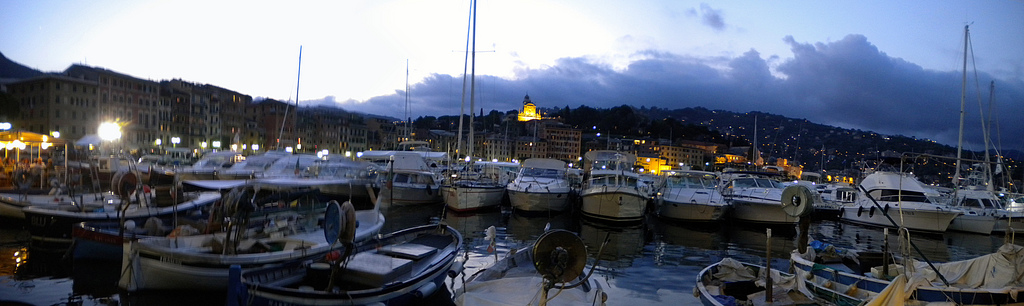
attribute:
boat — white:
[416, 103, 527, 248]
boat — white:
[170, 200, 572, 289]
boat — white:
[628, 166, 851, 300]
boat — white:
[575, 139, 656, 228]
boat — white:
[651, 161, 731, 226]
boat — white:
[249, 39, 384, 202]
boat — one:
[24, 117, 225, 223]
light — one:
[67, 100, 145, 167]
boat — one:
[565, 158, 652, 239]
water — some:
[24, 128, 977, 275]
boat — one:
[638, 163, 736, 241]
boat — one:
[709, 175, 831, 247]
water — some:
[1, 95, 1006, 292]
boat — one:
[843, 163, 984, 241]